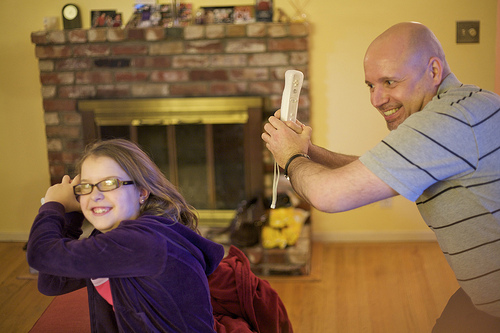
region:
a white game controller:
[276, 67, 304, 129]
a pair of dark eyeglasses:
[66, 177, 144, 195]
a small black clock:
[57, 3, 84, 25]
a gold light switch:
[452, 17, 484, 45]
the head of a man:
[354, 21, 453, 129]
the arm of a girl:
[26, 202, 165, 273]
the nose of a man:
[372, 81, 388, 106]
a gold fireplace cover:
[82, 98, 269, 228]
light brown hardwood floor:
[269, 243, 493, 331]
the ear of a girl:
[137, 186, 147, 203]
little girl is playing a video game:
[31, 96, 218, 325]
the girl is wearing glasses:
[24, 143, 135, 206]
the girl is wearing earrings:
[132, 175, 155, 210]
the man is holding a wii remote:
[225, 20, 460, 226]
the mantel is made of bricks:
[31, 17, 311, 187]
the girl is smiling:
[42, 107, 171, 232]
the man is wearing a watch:
[262, 144, 308, 189]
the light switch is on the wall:
[439, 10, 489, 55]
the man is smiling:
[344, 20, 439, 125]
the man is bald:
[337, 10, 452, 78]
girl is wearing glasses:
[68, 147, 174, 228]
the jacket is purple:
[34, 215, 214, 331]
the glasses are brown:
[75, 177, 138, 190]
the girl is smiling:
[73, 149, 135, 236]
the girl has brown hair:
[78, 136, 194, 238]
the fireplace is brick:
[35, 36, 313, 263]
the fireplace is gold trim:
[75, 92, 261, 230]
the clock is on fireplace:
[54, 6, 304, 254]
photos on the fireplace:
[82, 11, 212, 53]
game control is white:
[268, 64, 308, 133]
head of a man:
[361, 46, 397, 64]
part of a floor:
[363, 251, 402, 276]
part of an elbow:
[296, 173, 346, 250]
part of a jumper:
[149, 271, 188, 325]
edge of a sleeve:
[377, 157, 415, 211]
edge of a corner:
[359, 232, 403, 253]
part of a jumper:
[228, 266, 252, 318]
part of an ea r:
[124, 169, 152, 196]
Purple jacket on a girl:
[10, 200, 240, 331]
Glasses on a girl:
[58, 165, 142, 231]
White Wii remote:
[258, 71, 325, 166]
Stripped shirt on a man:
[351, 33, 498, 276]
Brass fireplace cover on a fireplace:
[67, 89, 254, 244]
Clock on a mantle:
[55, 1, 107, 43]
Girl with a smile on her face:
[30, 138, 250, 317]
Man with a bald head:
[353, 18, 467, 143]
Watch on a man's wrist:
[268, 139, 312, 180]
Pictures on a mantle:
[41, 0, 321, 30]